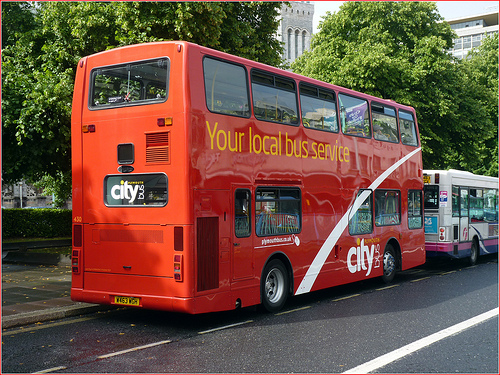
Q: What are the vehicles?
A: Buses.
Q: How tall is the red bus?
A: A double decker.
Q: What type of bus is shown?
A: A city bus.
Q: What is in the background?
A: Trees and buildings.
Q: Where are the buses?
A: On the road.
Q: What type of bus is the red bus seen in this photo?
A: City.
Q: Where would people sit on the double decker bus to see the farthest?
A: Top.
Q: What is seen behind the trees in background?
A: Buildings.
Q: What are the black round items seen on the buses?
A: Tires.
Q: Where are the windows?
A: Bus.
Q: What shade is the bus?
A: Red.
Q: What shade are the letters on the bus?
A: Yellow.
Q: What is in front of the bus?
A: A smaller bus.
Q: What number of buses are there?
A: Two.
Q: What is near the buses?
A: Trees.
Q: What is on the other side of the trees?
A: Building.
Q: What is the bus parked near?
A: Curb.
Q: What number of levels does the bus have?
A: Two.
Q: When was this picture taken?
A: Day time.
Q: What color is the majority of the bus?
A: Red.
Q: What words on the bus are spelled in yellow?
A: Your local bus service.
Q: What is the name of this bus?
A: City Bus.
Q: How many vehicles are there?
A: Two.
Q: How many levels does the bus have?
A: Two.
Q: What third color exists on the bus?
A: White.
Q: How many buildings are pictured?
A: Two.